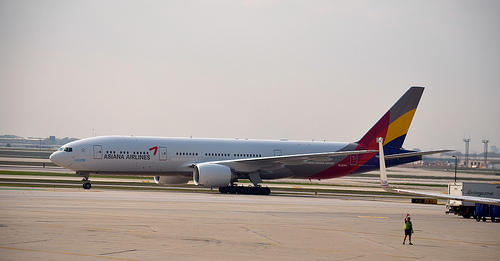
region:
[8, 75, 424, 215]
plane on the runway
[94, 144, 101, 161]
window on the plane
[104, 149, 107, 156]
window on the plane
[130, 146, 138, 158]
window on the plane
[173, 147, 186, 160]
window on the plane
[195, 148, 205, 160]
window on the plane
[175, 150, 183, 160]
window on the plane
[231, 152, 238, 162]
window on the plane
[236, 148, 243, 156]
window on the plane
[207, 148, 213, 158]
window on the plane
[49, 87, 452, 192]
airplane sitting on the air strip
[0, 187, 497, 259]
air strip plane is sitting on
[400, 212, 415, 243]
man standing on the air strip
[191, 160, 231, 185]
left engine of the airplane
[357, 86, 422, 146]
stabilizer of the airplane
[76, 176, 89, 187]
nose wheel of the airplane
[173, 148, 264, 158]
passenger window on the left side of the plane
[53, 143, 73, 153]
cockpit window of the airplane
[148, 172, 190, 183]
right engine of the airplane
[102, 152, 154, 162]
airline name on the left side of the plane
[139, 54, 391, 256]
a plane on teh groudn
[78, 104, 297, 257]
an airplane on the ground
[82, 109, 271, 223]
a large plane on the ground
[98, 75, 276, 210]
a large airplane on teh ground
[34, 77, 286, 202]
a white airplane on the ground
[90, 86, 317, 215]
a white plane on the ground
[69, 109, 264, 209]
a passenger plane on the ground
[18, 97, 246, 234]
a passenger airplane on the ground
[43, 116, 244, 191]
a large passenger airplane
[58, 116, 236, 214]
a large passenger plane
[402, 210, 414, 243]
a person on the runway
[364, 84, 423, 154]
the tail in multicolored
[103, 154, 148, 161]
black lettering on the plane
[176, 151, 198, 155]
passenger window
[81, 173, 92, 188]
landing gear is down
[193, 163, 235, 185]
a large wing engine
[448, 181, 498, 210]
a white box truck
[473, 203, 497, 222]
blue luggage cart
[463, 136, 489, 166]
two towers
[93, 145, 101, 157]
front passenger door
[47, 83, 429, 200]
a white commercial jet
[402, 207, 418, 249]
a runway ground crew member with their hand in the air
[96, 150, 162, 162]
black paint on a plane that reads asiana airlines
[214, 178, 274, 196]
black jet landing gear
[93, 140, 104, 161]
a door on a jet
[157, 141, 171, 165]
a door on a jet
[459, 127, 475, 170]
a metal runway tower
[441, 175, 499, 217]
a white flatbed truck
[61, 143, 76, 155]
a jet cock pit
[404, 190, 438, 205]
yellow and black runway markers